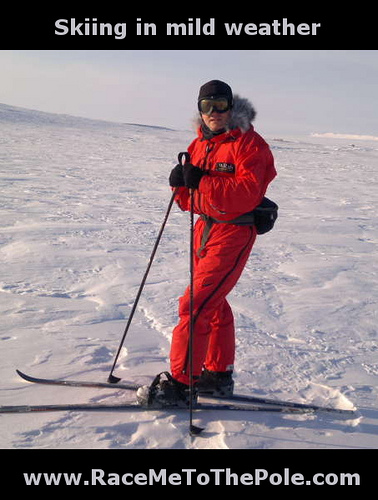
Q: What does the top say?
A: Skiing in mild weather.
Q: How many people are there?
A: One.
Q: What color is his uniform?
A: Orange.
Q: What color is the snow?
A: White.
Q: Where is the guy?
A: In the snow.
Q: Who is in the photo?
A: A guy.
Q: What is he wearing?
A: A ski suit.